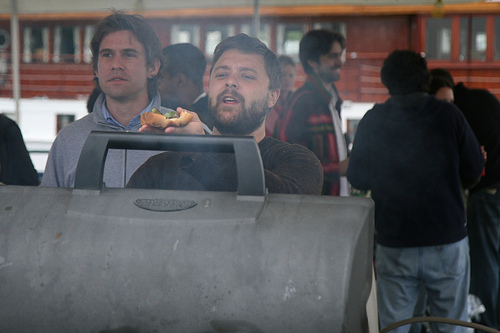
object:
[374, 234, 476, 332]
jeans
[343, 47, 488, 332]
man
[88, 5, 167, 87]
brown hair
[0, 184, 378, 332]
grill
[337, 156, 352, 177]
manhand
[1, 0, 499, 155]
building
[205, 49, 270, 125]
face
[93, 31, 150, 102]
face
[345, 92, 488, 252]
shirt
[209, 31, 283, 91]
hair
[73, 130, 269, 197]
brown tail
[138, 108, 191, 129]
bun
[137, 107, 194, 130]
sandwich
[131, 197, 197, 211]
emblem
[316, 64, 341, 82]
beard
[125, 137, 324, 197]
dark sweater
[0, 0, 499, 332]
background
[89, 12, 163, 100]
head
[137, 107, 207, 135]
hand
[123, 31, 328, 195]
man